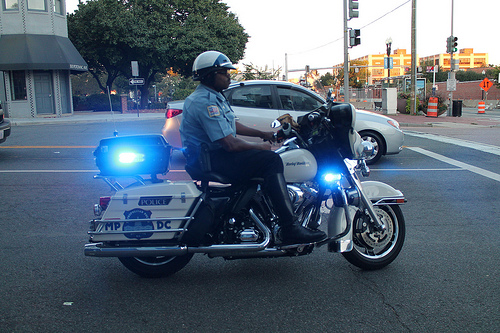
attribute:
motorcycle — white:
[85, 92, 408, 277]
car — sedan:
[164, 76, 404, 164]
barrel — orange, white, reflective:
[428, 94, 438, 120]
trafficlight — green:
[446, 35, 461, 55]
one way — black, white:
[126, 76, 148, 87]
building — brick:
[355, 46, 414, 87]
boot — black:
[257, 173, 324, 244]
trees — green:
[68, 2, 247, 113]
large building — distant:
[423, 50, 490, 72]